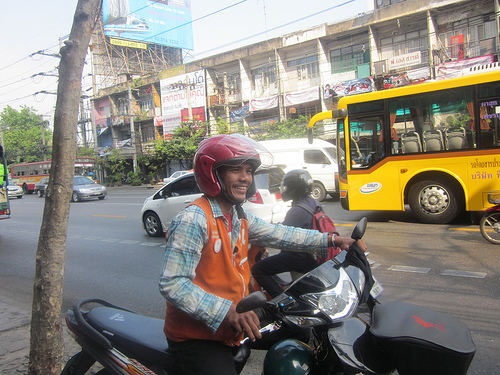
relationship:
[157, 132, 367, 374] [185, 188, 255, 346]
cyclist wearing vest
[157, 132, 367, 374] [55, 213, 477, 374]
cyclist on motorcycle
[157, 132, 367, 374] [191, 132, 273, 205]
cyclist in helmet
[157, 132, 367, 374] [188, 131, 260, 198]
cyclist in helmet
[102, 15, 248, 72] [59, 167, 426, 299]
power lines in road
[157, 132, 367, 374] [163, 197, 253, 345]
cyclist in orange vest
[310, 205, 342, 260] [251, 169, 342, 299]
backpack in man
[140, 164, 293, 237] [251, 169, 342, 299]
car in man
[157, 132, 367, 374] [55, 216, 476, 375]
cyclist in motorcycle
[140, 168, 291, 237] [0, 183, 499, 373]
car in street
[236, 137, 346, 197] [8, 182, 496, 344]
van in street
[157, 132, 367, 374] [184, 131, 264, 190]
cyclist wearing helmet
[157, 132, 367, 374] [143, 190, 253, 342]
cyclist wearing shirt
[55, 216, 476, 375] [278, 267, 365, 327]
motorcycle has a head light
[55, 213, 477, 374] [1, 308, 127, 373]
motorcycle on sidewalk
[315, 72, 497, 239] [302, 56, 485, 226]
bus in background